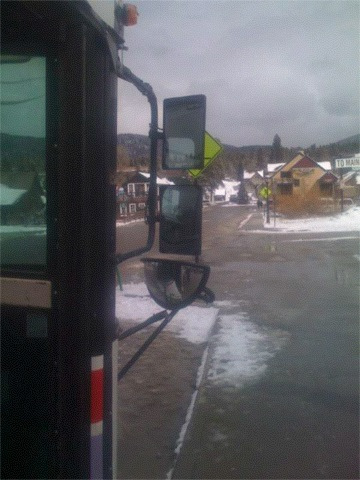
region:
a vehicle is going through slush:
[11, 0, 262, 466]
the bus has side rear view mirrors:
[15, 59, 216, 469]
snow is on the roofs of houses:
[123, 158, 357, 224]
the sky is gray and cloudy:
[85, 2, 359, 147]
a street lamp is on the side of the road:
[260, 174, 276, 227]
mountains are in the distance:
[5, 123, 358, 225]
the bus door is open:
[4, 6, 80, 474]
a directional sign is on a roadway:
[334, 153, 359, 170]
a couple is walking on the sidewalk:
[249, 196, 267, 231]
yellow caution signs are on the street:
[181, 126, 275, 202]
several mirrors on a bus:
[136, 88, 216, 331]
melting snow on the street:
[116, 258, 298, 386]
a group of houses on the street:
[230, 139, 358, 216]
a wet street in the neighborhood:
[131, 234, 353, 474]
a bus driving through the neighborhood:
[2, 4, 235, 478]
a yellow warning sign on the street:
[161, 114, 226, 192]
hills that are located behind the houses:
[121, 126, 357, 163]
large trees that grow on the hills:
[246, 132, 359, 160]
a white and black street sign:
[323, 153, 358, 171]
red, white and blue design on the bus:
[76, 338, 123, 479]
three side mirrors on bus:
[142, 87, 221, 313]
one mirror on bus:
[154, 85, 225, 174]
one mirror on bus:
[149, 176, 214, 262]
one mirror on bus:
[144, 254, 220, 314]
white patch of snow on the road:
[208, 290, 281, 393]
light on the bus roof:
[121, 0, 144, 27]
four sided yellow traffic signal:
[258, 182, 274, 202]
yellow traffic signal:
[206, 125, 228, 175]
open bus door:
[12, 15, 99, 476]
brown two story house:
[267, 152, 348, 217]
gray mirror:
[138, 90, 215, 308]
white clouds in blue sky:
[149, 11, 209, 48]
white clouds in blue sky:
[145, 38, 191, 58]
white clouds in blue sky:
[186, 13, 237, 56]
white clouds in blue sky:
[152, 53, 236, 91]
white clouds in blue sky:
[203, 12, 292, 45]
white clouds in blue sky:
[285, 16, 332, 54]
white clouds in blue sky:
[208, 33, 260, 81]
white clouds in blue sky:
[246, 52, 343, 114]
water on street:
[255, 251, 324, 346]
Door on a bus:
[1, 1, 122, 477]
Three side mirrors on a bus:
[109, 36, 207, 382]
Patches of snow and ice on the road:
[115, 279, 288, 397]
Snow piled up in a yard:
[264, 209, 358, 233]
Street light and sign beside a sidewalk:
[256, 174, 270, 227]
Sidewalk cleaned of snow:
[238, 210, 267, 234]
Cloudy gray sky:
[121, 0, 355, 152]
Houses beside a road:
[235, 150, 339, 214]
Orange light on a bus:
[113, 0, 138, 39]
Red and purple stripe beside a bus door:
[66, 352, 108, 478]